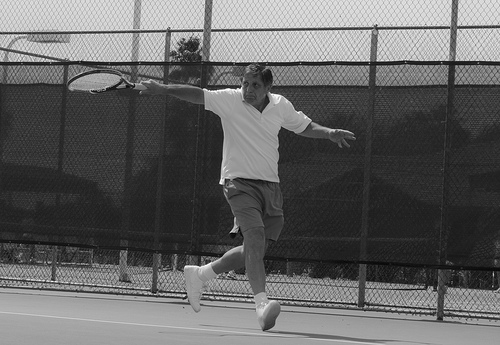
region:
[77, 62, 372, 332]
man in white shirt playing tennis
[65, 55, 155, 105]
tennis racquet used by a man playing the game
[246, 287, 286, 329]
tennis shoes in motion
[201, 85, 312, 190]
white shirt on a man playing tennis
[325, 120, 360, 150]
man's hand as he runs to hit tennis ball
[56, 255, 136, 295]
chain link fence around tennis court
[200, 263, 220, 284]
white socks on a man playing tennis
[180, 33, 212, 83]
tree outside tennis court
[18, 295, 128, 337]
outdoor tennis court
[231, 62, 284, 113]
shadow of a man running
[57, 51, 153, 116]
A tennis racket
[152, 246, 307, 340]
Feet of a man playing tennis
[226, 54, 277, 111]
A man concentrating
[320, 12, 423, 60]
A wire fence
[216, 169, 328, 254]
Shorts a man is wearing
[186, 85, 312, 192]
A white tennis shirt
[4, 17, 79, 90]
a lightpost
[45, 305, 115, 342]
Part of a tennis court including a serving line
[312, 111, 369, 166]
A man's hand raised while playing tennis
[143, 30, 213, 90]
A small scrubby tree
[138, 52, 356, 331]
man in white t-shirt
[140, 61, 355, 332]
man in white tennis shoes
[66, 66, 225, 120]
right are raising tennis racquet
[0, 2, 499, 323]
tall chain link fence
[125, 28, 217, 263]
tree visible through fence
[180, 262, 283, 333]
two feet off ground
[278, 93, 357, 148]
left arm out to side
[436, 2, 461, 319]
chain link fence post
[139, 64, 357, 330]
man in dark shorts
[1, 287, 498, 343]
tennis court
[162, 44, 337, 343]
a middle-aged man playing tennis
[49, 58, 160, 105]
the tennis racket the man is holding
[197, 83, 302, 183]
the white shirt the man is wearing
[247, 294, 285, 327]
the man's right foot with a white shoe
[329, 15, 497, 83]
the top of a chain-link fence at a tennis court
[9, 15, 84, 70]
a light in the next court for use at night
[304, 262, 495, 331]
the bottom of a chain link fence at the tennis court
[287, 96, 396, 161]
the man's right arm is extended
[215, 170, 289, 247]
the man is wearing shorts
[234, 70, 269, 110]
the man looks very serious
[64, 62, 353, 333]
a man playing tennis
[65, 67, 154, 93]
a tennis racket in a man's hand.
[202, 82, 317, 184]
a white shirt on a man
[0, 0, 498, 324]
chain link fencing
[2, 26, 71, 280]
street light behind fencing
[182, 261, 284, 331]
bright white shoes on man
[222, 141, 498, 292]
house behind fencing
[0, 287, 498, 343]
tennis court with white line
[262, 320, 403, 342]
shadow from man on court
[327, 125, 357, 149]
fingers on man's left hand spread apart